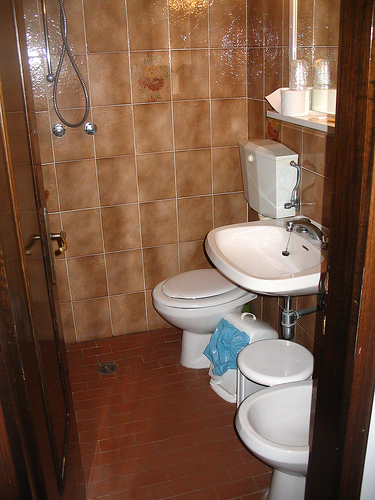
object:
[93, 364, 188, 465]
brick tiles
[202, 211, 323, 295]
porcelain sink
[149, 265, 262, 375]
white toilet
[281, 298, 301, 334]
pipes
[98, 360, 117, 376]
plughole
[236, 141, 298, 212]
tank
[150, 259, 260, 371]
toilet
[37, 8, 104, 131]
shower hose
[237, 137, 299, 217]
flushing system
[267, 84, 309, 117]
roll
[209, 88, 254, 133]
ground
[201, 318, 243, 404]
bag container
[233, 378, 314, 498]
toilet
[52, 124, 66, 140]
knob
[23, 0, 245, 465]
shower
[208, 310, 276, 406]
can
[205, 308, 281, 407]
basket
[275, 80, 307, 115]
toilet paper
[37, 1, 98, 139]
shower faucet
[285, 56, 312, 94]
cups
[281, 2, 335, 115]
mirror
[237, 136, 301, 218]
cistern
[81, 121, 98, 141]
knobs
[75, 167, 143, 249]
tiles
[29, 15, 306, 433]
wall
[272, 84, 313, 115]
paper roll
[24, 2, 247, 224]
tiles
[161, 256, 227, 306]
seat lid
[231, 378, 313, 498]
bidet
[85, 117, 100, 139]
water knob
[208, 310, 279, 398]
garbage can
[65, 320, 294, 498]
floor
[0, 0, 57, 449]
wooden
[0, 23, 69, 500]
door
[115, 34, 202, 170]
wall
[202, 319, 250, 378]
plastic bag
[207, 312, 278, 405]
trash can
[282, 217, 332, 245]
faucet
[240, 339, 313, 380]
equipment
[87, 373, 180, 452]
tiles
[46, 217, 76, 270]
handle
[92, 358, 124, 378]
drain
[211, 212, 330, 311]
wash basin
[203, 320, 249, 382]
bag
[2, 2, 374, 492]
bathroom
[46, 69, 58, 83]
shower head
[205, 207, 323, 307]
sink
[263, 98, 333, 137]
shelf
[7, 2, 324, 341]
bathroom walls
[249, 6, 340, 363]
wall